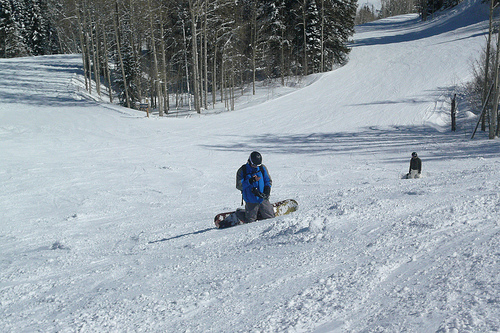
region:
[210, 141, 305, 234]
a skater on the snow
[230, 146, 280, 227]
skater is kneeling on snow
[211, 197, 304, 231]
a snowboard on the snow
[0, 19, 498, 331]
a field covered with snow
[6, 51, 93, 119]
shadows cast on snow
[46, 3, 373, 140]
trees on the snow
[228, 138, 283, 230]
person wears a blue coat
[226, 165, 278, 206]
blue snow coat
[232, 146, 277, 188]
person wears googles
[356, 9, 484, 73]
shadows cast on the snow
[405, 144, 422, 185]
Boy with black jacket kneeling down.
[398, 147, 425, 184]
Someone sitting down in the snow.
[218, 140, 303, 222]
Someone kneeling down on snow board.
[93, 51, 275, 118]
Group of trees surrounding snow.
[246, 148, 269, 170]
Black helmet on man's head.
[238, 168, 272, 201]
Blue jacket on someone's body.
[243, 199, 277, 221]
Grey sweatpants on a body.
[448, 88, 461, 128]
Small brown tree stump in snow.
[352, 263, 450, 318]
Traces of snowmobile in snow.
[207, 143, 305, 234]
person on a snowboard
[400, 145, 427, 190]
person on a snowboard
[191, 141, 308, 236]
person wearing blue jacket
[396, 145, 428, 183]
person wearing blue jacket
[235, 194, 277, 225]
pair of grey pants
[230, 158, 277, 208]
blue and grey jacket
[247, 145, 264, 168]
blue helmet on head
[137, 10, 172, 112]
trunk of a tree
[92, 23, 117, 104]
trunk of a tree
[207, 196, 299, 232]
snowboard covered in snow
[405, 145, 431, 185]
person kneeling on snow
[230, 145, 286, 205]
man wearing a blue jacket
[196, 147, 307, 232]
person kneeling on snow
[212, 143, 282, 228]
person wearing snow clothes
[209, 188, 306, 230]
person wearing snowboard on feet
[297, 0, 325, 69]
tall skinny snow covered tree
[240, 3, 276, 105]
tall skinny snow covered tree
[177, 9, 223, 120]
tall skinny snow covered tree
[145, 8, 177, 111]
tall skinny snow covered tree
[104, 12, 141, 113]
tall skinny snow covered tree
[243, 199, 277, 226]
the person is on his knees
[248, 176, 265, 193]
the coat is blue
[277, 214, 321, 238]
the snow is clumpy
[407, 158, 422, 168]
the coat is black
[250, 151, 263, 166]
the helmet is black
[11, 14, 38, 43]
the tree has snow on it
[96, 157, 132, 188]
the snow is white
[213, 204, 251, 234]
the person is hooked to the board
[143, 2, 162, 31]
the tree is bare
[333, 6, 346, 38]
the tree is green